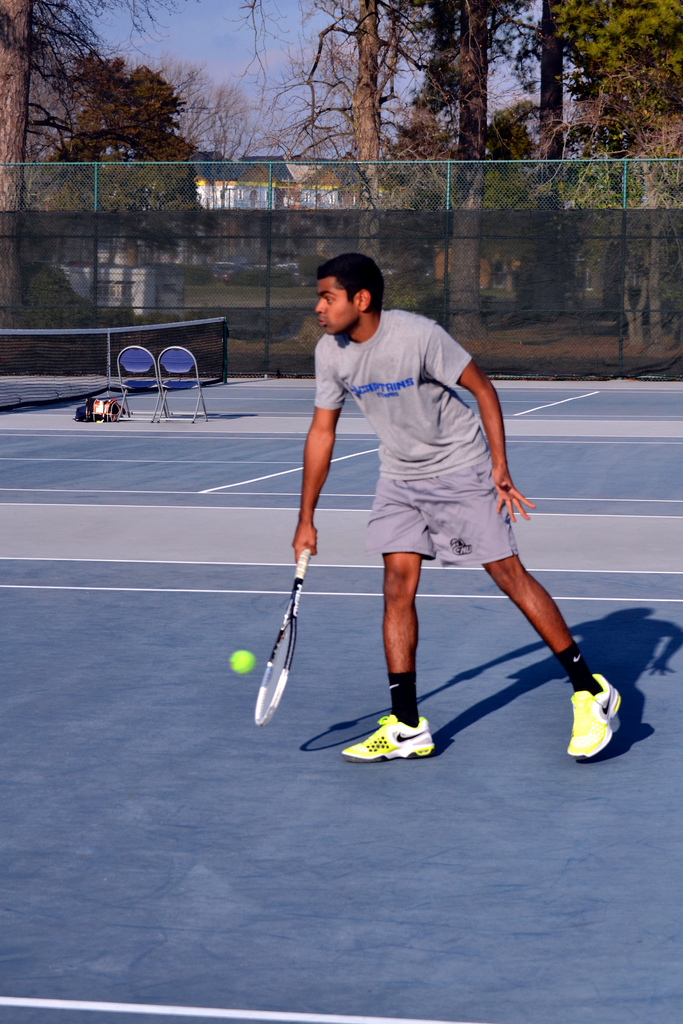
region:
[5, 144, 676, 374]
a tall chain link fence painted green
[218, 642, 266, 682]
a bright green tennis ball in motion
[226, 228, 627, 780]
a young man playing tennis outside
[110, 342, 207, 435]
a pair of blue folding chairs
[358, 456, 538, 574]
a pair of grey athletic shorts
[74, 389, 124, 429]
a black and white tennis bag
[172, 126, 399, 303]
a large, colorful building in the distance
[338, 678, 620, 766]
Yellow and white tennis shoes.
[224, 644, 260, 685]
A green tennis ball.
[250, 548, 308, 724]
Black and white tennis racket.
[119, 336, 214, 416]
Pair of metal folding chairs.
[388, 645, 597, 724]
Pair of black nike socks.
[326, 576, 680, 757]
Shadow of tennis player.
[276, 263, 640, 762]
A male tennis player.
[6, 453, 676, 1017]
Tennis half court is green and white.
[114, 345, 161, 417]
the blue fold up chair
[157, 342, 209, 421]
the blue fold up chair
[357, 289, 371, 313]
the ear of the tennis player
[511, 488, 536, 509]
the long finger of the hand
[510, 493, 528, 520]
the long finger of the hand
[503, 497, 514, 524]
the long finger of the hand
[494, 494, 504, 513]
the long finger of the hand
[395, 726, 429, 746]
the black nike swoop logo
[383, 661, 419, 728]
the black tall sock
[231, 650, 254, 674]
the tennis ball is green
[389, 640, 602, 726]
the socks are black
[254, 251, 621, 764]
the man holding the racket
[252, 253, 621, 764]
the man is wearing a shirt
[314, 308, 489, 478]
the shirt is gray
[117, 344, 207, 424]
the chairs are blue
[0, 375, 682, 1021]
the floor of the tennis court is blue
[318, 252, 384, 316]
the hair is short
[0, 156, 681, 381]
the fenceis tall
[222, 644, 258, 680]
a tennis ball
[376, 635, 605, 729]
a pair of black socks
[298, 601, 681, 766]
shadow of a tennis player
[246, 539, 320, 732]
white-and-black tennis racket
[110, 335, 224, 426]
two blue-and-gray folding chairs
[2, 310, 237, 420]
a tennis net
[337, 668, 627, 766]
pair of white-and-yellow tennis shoes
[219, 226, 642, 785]
a man hitting a ball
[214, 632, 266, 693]
the ball is green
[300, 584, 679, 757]
shadow on the ground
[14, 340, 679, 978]
the court is blue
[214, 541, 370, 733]
a black and white racket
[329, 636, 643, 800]
a pair of tennis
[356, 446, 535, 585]
a pair of gray shorts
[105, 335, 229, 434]
a pair of shorts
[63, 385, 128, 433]
equipment on the court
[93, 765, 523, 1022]
this is a tennis court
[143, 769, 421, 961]
the court is blue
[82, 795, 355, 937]
the court is clay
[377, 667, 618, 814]
the shoes are yellow and white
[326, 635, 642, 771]
the shoes are nikes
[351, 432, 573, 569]
the shorts are gray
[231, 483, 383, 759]
this is a tennis racket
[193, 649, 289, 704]
the ball is neon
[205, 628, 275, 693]
the ball is green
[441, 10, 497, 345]
A tree in a city.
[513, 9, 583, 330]
A tree in a city.